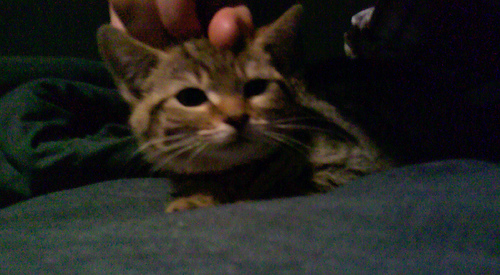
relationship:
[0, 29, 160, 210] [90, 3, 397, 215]
blanket next to cat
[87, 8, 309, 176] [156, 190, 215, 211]
head elevated over paw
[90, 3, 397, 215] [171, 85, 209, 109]
cat has black eyes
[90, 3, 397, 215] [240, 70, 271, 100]
cat has eye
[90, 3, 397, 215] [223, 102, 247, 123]
cat has nose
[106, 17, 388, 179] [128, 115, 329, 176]
cat has whiskers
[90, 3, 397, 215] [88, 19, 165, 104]
cat has ear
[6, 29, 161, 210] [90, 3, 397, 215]
blanket near cat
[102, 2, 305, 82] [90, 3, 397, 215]
person petting cat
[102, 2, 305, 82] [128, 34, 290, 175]
person petting head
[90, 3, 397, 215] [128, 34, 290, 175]
cat has head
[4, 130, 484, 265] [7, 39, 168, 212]
bed has blanket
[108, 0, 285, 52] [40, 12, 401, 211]
hand petting head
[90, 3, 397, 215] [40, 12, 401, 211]
cat has head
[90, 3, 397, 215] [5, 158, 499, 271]
cat lying on bed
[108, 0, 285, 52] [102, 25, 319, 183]
hand rubbing head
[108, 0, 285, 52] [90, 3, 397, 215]
hand rubbing cat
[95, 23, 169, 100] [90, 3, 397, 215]
ear of cat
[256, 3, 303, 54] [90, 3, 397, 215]
ear of cat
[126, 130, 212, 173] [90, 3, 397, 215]
whiskers of cat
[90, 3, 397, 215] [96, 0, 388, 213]
cat below head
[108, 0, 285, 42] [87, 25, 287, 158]
hand on head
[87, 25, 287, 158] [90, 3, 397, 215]
head of cat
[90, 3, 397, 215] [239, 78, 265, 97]
cat with eye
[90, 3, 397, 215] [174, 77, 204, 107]
cat with eye